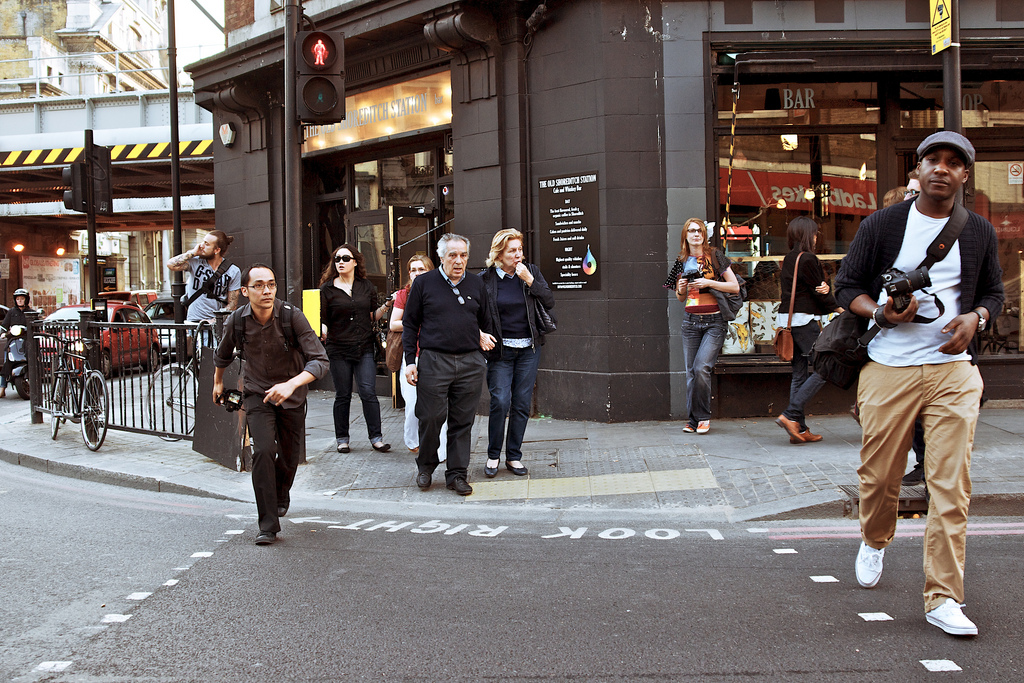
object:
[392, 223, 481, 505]
person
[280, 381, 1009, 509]
sidewalk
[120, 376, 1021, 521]
sidewalk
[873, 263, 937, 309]
camera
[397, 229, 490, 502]
man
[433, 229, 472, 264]
gray hair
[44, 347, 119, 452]
bike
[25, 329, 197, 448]
rail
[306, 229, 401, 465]
woman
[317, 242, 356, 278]
long hair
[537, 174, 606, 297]
sign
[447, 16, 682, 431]
wall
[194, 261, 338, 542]
person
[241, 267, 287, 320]
head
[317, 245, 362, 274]
head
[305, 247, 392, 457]
person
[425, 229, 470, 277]
head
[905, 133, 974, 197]
head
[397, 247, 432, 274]
head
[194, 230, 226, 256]
head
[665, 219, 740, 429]
person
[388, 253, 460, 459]
person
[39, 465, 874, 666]
street corner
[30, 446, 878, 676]
street corner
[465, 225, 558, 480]
person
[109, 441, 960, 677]
street corner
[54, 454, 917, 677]
street corner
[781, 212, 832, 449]
person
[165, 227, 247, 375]
person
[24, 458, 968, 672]
street corner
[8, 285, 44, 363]
person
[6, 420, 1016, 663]
street corner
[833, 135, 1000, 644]
man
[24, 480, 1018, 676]
street